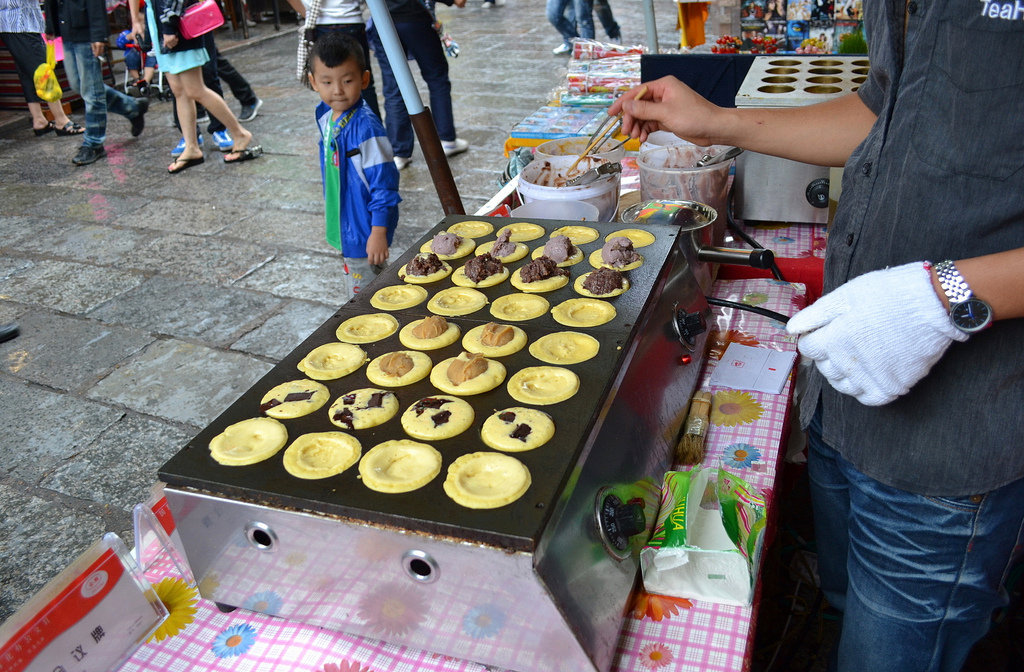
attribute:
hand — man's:
[775, 258, 957, 423]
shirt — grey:
[781, 8, 1023, 486]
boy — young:
[289, 21, 436, 300]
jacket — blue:
[304, 99, 413, 270]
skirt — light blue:
[142, 10, 236, 86]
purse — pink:
[175, 1, 249, 58]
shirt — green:
[300, 108, 380, 247]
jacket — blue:
[301, 103, 397, 250]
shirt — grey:
[796, 1, 1016, 501]